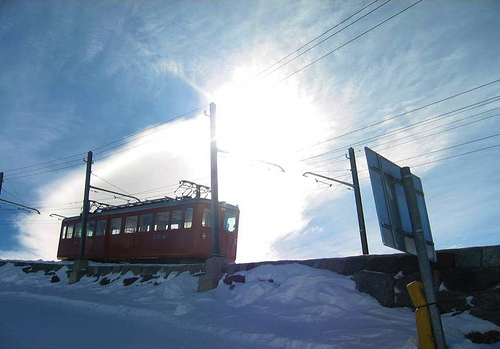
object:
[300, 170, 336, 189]
light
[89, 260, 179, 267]
snow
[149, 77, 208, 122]
cloud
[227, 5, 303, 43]
cloud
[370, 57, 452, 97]
cloud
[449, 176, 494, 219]
cloud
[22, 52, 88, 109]
cloud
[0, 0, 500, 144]
sky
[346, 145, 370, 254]
pole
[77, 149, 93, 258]
pole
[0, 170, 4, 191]
pole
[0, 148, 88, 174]
electric lines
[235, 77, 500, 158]
line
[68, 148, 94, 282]
pole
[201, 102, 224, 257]
pole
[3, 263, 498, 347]
snow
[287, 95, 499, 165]
line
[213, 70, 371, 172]
sunlight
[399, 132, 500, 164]
electrical wires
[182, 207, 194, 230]
windows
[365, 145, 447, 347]
sign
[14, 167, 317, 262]
cloud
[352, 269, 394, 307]
rock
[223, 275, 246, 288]
rock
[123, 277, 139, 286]
rock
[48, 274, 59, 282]
rock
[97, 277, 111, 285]
rock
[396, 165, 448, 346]
sign pole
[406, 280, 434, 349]
yellow pole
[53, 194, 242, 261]
train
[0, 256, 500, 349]
ground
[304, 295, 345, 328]
part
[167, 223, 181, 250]
part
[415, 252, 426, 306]
edge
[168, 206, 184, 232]
windows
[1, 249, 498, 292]
tracks